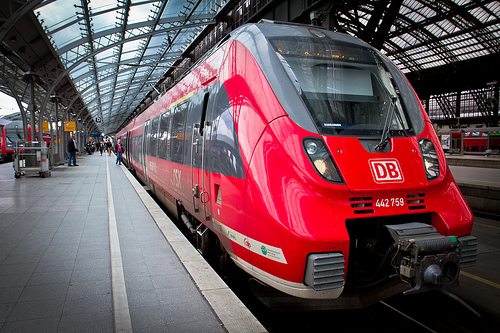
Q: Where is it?
A: This is at the station.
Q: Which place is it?
A: It is a station.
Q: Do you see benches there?
A: No, there are no benches.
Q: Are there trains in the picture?
A: Yes, there is a train.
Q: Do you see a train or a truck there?
A: Yes, there is a train.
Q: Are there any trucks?
A: No, there are no trucks.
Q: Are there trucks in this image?
A: No, there are no trucks.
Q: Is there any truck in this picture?
A: No, there are no trucks.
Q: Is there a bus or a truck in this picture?
A: No, there are no trucks or buses.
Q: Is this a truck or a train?
A: This is a train.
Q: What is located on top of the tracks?
A: The train is on top of the tracks.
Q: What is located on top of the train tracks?
A: The train is on top of the tracks.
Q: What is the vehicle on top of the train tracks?
A: The vehicle is a train.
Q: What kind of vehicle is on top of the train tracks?
A: The vehicle is a train.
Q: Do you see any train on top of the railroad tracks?
A: Yes, there is a train on top of the railroad tracks.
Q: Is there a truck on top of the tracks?
A: No, there is a train on top of the tracks.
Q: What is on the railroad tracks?
A: The train is on the railroad tracks.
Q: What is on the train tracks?
A: The train is on the railroad tracks.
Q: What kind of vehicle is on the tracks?
A: The vehicle is a train.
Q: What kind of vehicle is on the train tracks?
A: The vehicle is a train.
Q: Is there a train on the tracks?
A: Yes, there is a train on the tracks.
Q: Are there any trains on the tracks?
A: Yes, there is a train on the tracks.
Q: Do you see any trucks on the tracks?
A: No, there is a train on the tracks.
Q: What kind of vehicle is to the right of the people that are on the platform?
A: The vehicle is a train.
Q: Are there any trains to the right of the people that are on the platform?
A: Yes, there is a train to the right of the people.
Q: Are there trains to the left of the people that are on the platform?
A: No, the train is to the right of the people.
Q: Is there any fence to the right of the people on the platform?
A: No, there is a train to the right of the people.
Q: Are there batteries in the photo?
A: No, there are no batteries.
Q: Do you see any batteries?
A: No, there are no batteries.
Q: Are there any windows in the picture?
A: Yes, there are windows.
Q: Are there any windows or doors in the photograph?
A: Yes, there are windows.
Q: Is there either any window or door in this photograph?
A: Yes, there are windows.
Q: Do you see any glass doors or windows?
A: Yes, there are glass windows.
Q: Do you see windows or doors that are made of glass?
A: Yes, the windows are made of glass.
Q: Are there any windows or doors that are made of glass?
A: Yes, the windows are made of glass.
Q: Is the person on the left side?
A: Yes, the person is on the left of the image.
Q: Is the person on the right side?
A: No, the person is on the left of the image.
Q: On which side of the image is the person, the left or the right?
A: The person is on the left of the image.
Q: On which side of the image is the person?
A: The person is on the left of the image.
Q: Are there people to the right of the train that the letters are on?
A: Yes, there is a person to the right of the train.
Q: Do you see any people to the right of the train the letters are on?
A: Yes, there is a person to the right of the train.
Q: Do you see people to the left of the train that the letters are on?
A: No, the person is to the right of the train.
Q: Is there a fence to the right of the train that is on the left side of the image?
A: No, there is a person to the right of the train.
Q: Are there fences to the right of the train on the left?
A: No, there is a person to the right of the train.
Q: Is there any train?
A: Yes, there is a train.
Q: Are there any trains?
A: Yes, there is a train.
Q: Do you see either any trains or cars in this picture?
A: Yes, there is a train.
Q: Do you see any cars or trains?
A: Yes, there is a train.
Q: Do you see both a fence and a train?
A: No, there is a train but no fences.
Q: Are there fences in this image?
A: No, there are no fences.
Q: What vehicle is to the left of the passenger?
A: The vehicle is a train.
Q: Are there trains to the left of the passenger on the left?
A: Yes, there is a train to the left of the passenger.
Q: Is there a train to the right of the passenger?
A: No, the train is to the left of the passenger.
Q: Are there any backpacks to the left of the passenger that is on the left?
A: No, there is a train to the left of the passenger.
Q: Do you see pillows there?
A: No, there are no pillows.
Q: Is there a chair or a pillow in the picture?
A: No, there are no pillows or chairs.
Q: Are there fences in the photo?
A: No, there are no fences.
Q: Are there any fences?
A: No, there are no fences.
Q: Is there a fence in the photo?
A: No, there are no fences.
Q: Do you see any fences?
A: No, there are no fences.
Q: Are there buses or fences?
A: No, there are no fences or buses.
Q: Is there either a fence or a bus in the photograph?
A: No, there are no fences or buses.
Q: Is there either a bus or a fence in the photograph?
A: No, there are no fences or buses.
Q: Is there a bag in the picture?
A: No, there are no bags.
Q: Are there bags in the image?
A: No, there are no bags.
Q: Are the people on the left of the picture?
A: Yes, the people are on the left of the image.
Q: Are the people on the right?
A: No, the people are on the left of the image.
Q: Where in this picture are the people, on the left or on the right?
A: The people are on the left of the image.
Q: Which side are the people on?
A: The people are on the left of the image.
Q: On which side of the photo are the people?
A: The people are on the left of the image.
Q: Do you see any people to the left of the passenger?
A: Yes, there are people to the left of the passenger.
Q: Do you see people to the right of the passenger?
A: No, the people are to the left of the passenger.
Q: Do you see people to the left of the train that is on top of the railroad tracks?
A: Yes, there are people to the left of the train.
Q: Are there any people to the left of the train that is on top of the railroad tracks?
A: Yes, there are people to the left of the train.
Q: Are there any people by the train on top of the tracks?
A: Yes, there are people by the train.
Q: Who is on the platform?
A: The people are on the platform.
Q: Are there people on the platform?
A: Yes, there are people on the platform.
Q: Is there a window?
A: Yes, there is a window.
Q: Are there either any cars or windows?
A: Yes, there is a window.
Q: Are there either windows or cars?
A: Yes, there is a window.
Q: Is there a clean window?
A: Yes, there is a clean window.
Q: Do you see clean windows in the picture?
A: Yes, there is a clean window.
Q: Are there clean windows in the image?
A: Yes, there is a clean window.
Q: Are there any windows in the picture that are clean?
A: Yes, there is a window that is clean.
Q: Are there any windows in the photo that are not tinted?
A: Yes, there is a clean window.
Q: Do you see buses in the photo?
A: No, there are no buses.